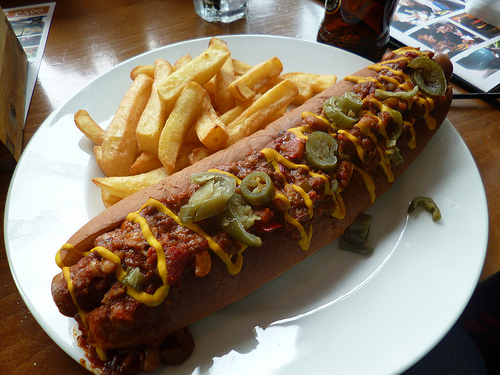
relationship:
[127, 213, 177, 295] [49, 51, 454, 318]
mustard drizzled on hot dog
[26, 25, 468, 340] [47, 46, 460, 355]
hot dog on roll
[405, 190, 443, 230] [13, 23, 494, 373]
slice on plate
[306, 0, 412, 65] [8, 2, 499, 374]
bottle on table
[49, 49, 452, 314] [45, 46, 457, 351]
weiner on hotdog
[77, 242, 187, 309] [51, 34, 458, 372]
chili on hot dog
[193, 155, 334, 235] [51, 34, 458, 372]
chili on hot dog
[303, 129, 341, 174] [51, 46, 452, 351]
jalapenos are on hot dog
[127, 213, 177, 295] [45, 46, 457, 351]
mustard are on hotdog